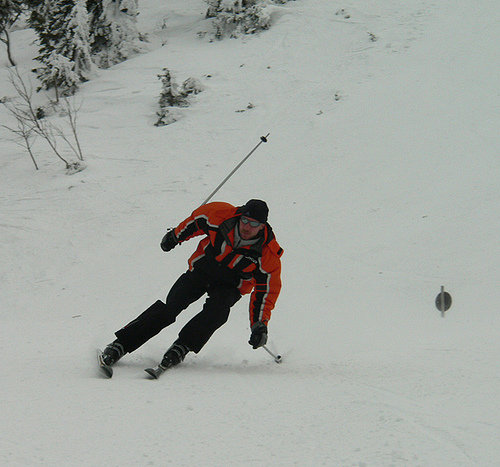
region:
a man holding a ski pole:
[181, 128, 271, 223]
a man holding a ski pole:
[253, 330, 283, 363]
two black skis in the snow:
[93, 336, 186, 379]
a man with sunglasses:
[236, 215, 263, 228]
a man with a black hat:
[238, 198, 270, 226]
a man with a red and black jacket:
[165, 195, 289, 330]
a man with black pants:
[113, 260, 247, 355]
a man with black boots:
[100, 337, 129, 364]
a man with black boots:
[160, 338, 191, 367]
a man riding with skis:
[95, 130, 285, 377]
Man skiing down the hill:
[72, 131, 293, 379]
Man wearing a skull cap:
[219, 193, 283, 259]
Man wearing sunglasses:
[223, 211, 267, 230]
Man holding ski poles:
[157, 130, 276, 260]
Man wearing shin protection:
[81, 262, 232, 386]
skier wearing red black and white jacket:
[151, 198, 298, 358]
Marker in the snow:
[430, 283, 467, 326]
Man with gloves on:
[238, 319, 278, 355]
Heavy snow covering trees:
[23, 11, 152, 125]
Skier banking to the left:
[93, 127, 288, 389]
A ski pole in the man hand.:
[248, 320, 306, 381]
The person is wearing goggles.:
[241, 217, 273, 230]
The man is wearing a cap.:
[238, 194, 289, 221]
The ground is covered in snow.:
[45, 318, 387, 465]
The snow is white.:
[45, 328, 460, 463]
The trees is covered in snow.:
[47, 9, 189, 94]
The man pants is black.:
[105, 279, 232, 346]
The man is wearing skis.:
[91, 345, 176, 389]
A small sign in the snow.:
[429, 266, 460, 321]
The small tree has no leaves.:
[9, 82, 97, 178]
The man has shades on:
[231, 200, 266, 242]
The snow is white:
[304, 133, 421, 270]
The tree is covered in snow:
[43, 19, 127, 96]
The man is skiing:
[91, 176, 306, 393]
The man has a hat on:
[224, 195, 281, 233]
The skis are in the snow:
[71, 325, 210, 399]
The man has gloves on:
[122, 208, 222, 267]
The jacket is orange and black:
[176, 194, 311, 338]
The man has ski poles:
[13, 121, 390, 353]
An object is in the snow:
[422, 278, 467, 327]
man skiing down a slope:
[61, 93, 350, 398]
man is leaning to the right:
[98, 193, 290, 385]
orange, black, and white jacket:
[163, 194, 299, 329]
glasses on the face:
[239, 215, 264, 227]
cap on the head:
[239, 197, 271, 222]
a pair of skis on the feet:
[88, 339, 180, 389]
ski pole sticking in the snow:
[246, 326, 299, 374]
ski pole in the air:
[173, 126, 286, 208]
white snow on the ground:
[0, 0, 499, 465]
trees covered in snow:
[23, 1, 155, 88]